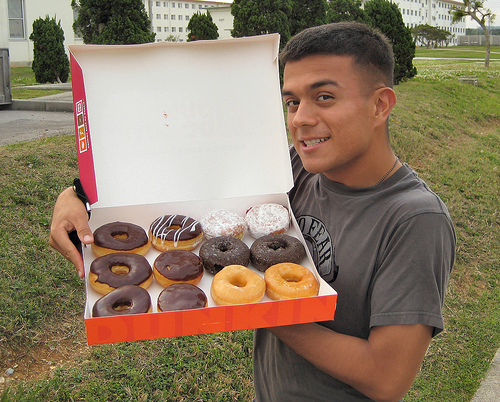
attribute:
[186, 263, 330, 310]
donuts — glazed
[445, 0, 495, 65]
tree — tall, leafy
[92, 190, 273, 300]
donuts —  a dozen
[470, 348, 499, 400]
sidewalk — paved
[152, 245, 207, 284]
donut — cream filled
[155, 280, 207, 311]
donut — cream filled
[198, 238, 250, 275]
donut — chocolate, cake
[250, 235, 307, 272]
donut — chocolate, cake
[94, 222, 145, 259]
donut — 12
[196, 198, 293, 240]
donuts — jelly filled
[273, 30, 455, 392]
boy — smiling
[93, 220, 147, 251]
donut — chocolate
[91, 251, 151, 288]
donut — chocolate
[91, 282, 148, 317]
donut — chocolate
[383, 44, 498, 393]
grass — dying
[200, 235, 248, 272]
donut — chocolate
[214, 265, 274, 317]
donut — glazed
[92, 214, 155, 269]
donut — chocolate, glazed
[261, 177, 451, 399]
shirt — grey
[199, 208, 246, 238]
donut — powdered, filled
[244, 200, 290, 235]
donut — filled, powdered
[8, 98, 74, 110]
curb —  concrete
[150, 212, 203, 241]
frosting — white, chocolate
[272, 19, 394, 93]
hair — short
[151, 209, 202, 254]
donut — chocolate, vanilla, glazed